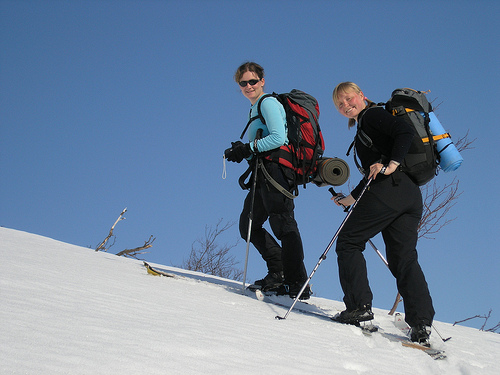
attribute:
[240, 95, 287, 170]
shirt — light, blue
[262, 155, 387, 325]
poles — ski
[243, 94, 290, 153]
shirt — aqua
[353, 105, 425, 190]
shirt — aqua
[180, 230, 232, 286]
trees — leafless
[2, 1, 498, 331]
sky — blue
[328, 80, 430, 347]
lady — smiling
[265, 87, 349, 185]
backpack — orange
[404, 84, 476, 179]
bed mat — blue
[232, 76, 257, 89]
sunglasses — dark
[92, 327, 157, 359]
snow — white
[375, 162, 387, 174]
strap — pole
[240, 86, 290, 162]
shirt — blue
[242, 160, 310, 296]
pants — black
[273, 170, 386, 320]
pole — ski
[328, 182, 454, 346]
pole — ski